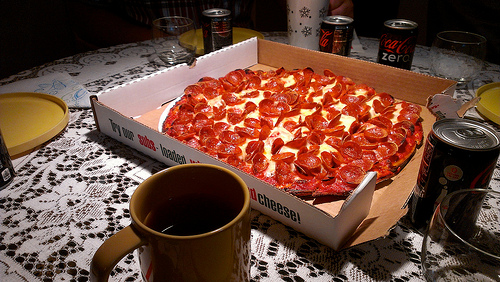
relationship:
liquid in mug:
[162, 217, 223, 232] [89, 161, 253, 281]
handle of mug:
[88, 223, 144, 280] [89, 161, 253, 281]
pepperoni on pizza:
[258, 99, 281, 117] [157, 67, 425, 200]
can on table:
[406, 118, 498, 241] [0, 23, 498, 280]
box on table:
[88, 37, 467, 247] [0, 23, 498, 280]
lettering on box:
[251, 193, 301, 226] [88, 37, 467, 247]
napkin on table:
[3, 69, 93, 108] [0, 23, 498, 280]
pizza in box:
[157, 67, 425, 200] [88, 37, 467, 247]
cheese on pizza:
[278, 125, 288, 143] [157, 67, 425, 200]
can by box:
[406, 118, 498, 241] [88, 37, 467, 247]